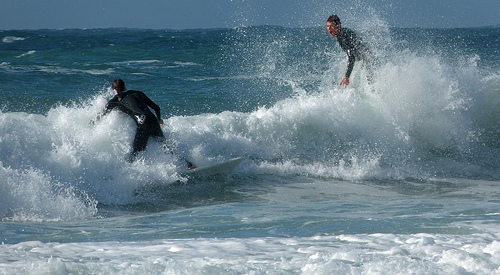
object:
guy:
[92, 75, 196, 167]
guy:
[320, 13, 383, 91]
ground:
[431, 143, 485, 195]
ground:
[383, 152, 400, 176]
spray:
[2, 0, 499, 221]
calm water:
[6, 26, 217, 71]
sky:
[1, 1, 498, 28]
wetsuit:
[313, 13, 412, 83]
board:
[186, 153, 244, 178]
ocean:
[195, 7, 489, 240]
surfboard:
[159, 152, 253, 182]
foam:
[1, 232, 497, 274]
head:
[324, 12, 341, 39]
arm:
[336, 42, 358, 85]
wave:
[3, 52, 495, 232]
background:
[4, 84, 498, 214]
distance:
[12, 67, 492, 137]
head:
[315, 54, 342, 75]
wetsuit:
[112, 77, 171, 169]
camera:
[92, 101, 223, 258]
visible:
[322, 49, 342, 82]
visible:
[278, 72, 392, 162]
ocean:
[4, 168, 498, 259]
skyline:
[48, 50, 132, 129]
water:
[2, 30, 496, 270]